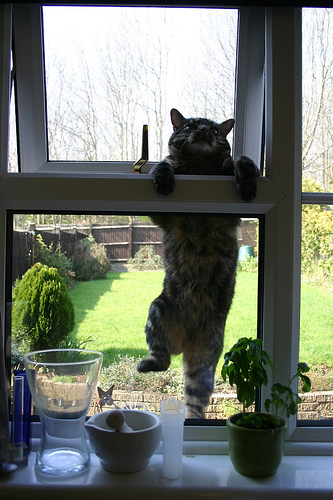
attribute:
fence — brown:
[16, 223, 163, 265]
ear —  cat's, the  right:
[165, 105, 181, 128]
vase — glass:
[16, 343, 115, 490]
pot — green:
[225, 410, 287, 479]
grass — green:
[64, 271, 331, 374]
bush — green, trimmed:
[1, 260, 82, 360]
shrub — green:
[10, 260, 78, 368]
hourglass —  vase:
[31, 349, 92, 477]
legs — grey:
[121, 151, 269, 210]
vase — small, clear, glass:
[21, 342, 102, 478]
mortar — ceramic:
[87, 407, 161, 479]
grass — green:
[49, 286, 328, 364]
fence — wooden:
[12, 221, 256, 276]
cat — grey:
[145, 86, 268, 409]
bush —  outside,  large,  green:
[6, 252, 101, 362]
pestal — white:
[83, 402, 161, 474]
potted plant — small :
[222, 336, 310, 476]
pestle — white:
[79, 406, 164, 475]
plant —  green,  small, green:
[221, 336, 310, 426]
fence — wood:
[9, 218, 261, 288]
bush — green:
[12, 258, 81, 358]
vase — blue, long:
[5, 367, 36, 456]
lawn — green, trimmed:
[74, 269, 331, 375]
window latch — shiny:
[131, 123, 151, 175]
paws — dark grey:
[137, 152, 277, 218]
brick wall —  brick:
[10, 366, 331, 420]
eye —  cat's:
[177, 121, 196, 133]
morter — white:
[69, 384, 167, 473]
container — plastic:
[140, 384, 196, 484]